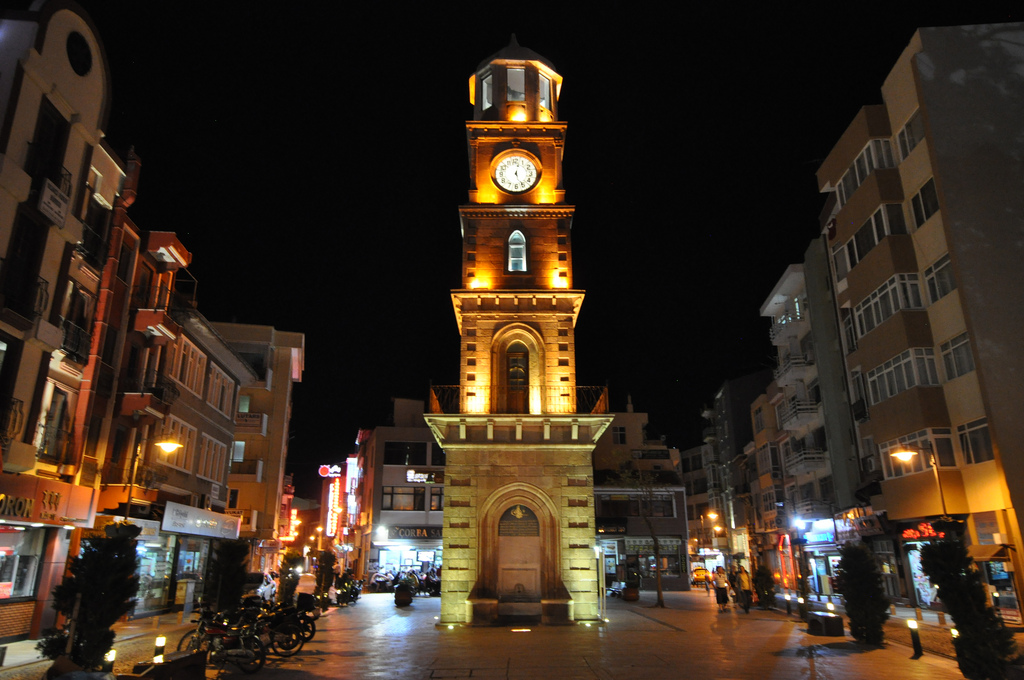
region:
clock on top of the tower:
[482, 148, 546, 188]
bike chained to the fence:
[189, 594, 303, 667]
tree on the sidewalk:
[204, 524, 266, 619]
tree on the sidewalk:
[265, 535, 308, 606]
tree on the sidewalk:
[303, 538, 351, 596]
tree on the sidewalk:
[16, 516, 185, 662]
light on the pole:
[894, 443, 911, 462]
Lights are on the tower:
[433, 59, 605, 626]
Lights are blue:
[363, 535, 441, 573]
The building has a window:
[497, 216, 530, 294]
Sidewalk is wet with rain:
[324, 624, 792, 675]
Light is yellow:
[874, 431, 922, 471]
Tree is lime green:
[36, 514, 134, 674]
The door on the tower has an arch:
[457, 478, 563, 608]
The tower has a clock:
[485, 144, 553, 215]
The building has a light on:
[752, 269, 813, 342]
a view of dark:
[271, 130, 408, 277]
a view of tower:
[372, 117, 720, 661]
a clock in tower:
[449, 135, 564, 203]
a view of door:
[451, 511, 581, 611]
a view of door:
[117, 511, 277, 668]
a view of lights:
[800, 481, 842, 535]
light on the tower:
[351, 521, 674, 649]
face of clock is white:
[490, 148, 548, 200]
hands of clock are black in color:
[508, 156, 525, 192]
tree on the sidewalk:
[46, 479, 155, 672]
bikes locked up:
[179, 599, 288, 673]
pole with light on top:
[945, 425, 996, 625]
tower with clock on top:
[446, 24, 614, 628]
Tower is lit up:
[424, 46, 633, 676]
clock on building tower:
[485, 148, 546, 197]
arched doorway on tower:
[482, 489, 552, 598]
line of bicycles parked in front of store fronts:
[179, 582, 326, 672]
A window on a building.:
[384, 435, 410, 467]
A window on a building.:
[403, 437, 426, 466]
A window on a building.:
[860, 299, 876, 328]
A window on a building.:
[932, 329, 981, 375]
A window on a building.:
[934, 425, 953, 461]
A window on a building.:
[384, 479, 426, 503]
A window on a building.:
[46, 380, 67, 466]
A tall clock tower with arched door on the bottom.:
[425, 27, 615, 629]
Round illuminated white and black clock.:
[490, 151, 539, 194]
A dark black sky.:
[94, 3, 901, 474]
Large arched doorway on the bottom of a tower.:
[477, 479, 566, 626]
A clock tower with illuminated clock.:
[420, 27, 620, 626]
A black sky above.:
[94, 5, 908, 495]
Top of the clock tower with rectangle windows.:
[461, 34, 566, 126]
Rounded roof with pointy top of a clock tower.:
[467, 30, 562, 101]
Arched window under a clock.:
[504, 230, 530, 275]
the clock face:
[490, 143, 536, 194]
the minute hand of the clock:
[512, 156, 526, 173]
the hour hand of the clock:
[513, 174, 526, 190]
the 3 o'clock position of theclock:
[525, 167, 539, 175]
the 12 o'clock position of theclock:
[509, 146, 523, 167]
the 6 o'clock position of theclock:
[513, 180, 520, 193]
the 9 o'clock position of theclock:
[492, 162, 505, 179]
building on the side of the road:
[735, 380, 819, 616]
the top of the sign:
[155, 493, 266, 522]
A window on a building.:
[852, 216, 882, 255]